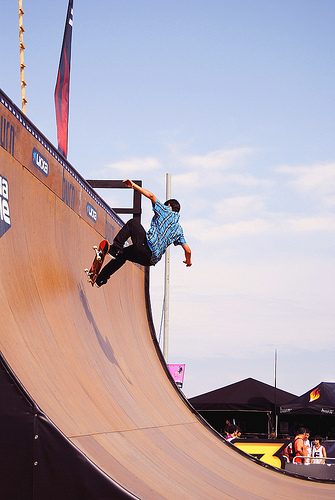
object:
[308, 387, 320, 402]
fire logo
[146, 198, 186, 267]
shirt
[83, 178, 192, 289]
boy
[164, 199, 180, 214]
head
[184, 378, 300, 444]
tent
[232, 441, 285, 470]
number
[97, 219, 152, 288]
pants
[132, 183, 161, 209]
skater's arms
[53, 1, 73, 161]
flag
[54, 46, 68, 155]
flame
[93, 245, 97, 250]
wheel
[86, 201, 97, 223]
logo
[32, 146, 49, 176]
logo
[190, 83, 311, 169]
sky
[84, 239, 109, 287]
skateboard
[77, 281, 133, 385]
shadow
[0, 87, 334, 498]
skating ramp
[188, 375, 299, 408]
roof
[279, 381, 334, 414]
roof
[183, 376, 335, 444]
building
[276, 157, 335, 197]
clouds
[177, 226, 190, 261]
arm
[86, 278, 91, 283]
wheel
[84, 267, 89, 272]
wheel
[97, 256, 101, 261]
wheel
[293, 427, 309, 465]
person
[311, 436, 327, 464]
person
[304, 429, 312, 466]
person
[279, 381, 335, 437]
tent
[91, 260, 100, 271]
design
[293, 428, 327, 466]
talking